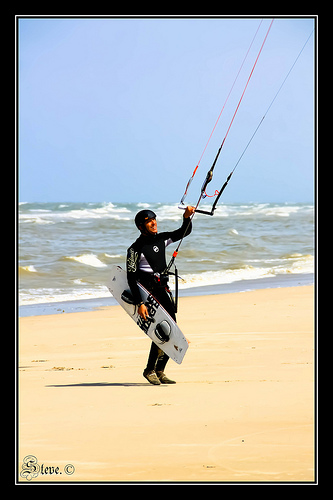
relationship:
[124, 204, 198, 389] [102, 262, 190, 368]
man holding kiteboard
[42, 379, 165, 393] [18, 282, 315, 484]
shadow cast onto beach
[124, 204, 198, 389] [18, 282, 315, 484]
man standing on beach